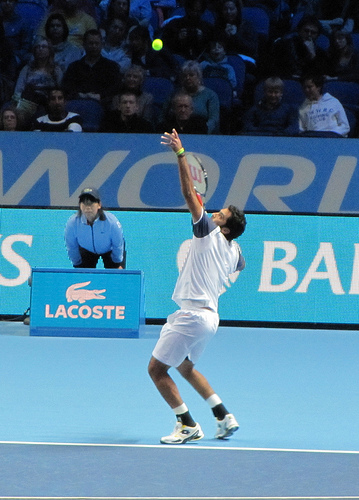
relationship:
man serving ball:
[148, 126, 248, 455] [150, 34, 167, 55]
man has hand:
[143, 122, 263, 454] [150, 130, 184, 153]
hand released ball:
[150, 130, 184, 153] [150, 34, 167, 55]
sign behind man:
[31, 271, 156, 336] [143, 122, 263, 454]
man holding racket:
[143, 122, 263, 454] [180, 147, 214, 214]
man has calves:
[143, 122, 263, 454] [162, 364, 220, 409]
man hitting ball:
[143, 122, 263, 454] [150, 34, 167, 55]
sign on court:
[31, 271, 156, 336] [5, 316, 358, 485]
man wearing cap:
[143, 122, 263, 454] [224, 198, 249, 235]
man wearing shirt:
[143, 122, 263, 454] [175, 200, 248, 312]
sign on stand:
[31, 271, 156, 336] [4, 207, 340, 313]